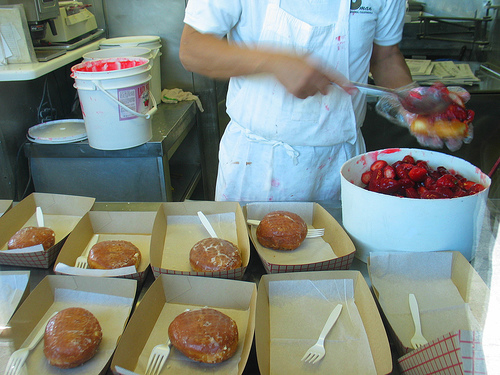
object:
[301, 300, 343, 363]
fork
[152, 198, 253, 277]
food tray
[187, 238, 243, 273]
donut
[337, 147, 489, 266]
bucket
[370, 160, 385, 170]
strawberries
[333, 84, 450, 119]
spoon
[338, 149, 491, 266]
pail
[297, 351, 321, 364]
tines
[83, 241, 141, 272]
pastry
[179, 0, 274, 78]
arm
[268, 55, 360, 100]
hand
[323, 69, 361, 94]
finger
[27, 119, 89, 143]
lid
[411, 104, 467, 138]
donut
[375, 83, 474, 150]
glove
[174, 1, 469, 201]
man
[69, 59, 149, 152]
bucket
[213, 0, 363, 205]
apron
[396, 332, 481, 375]
box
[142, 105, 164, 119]
handle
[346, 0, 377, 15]
emblem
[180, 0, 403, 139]
shirt